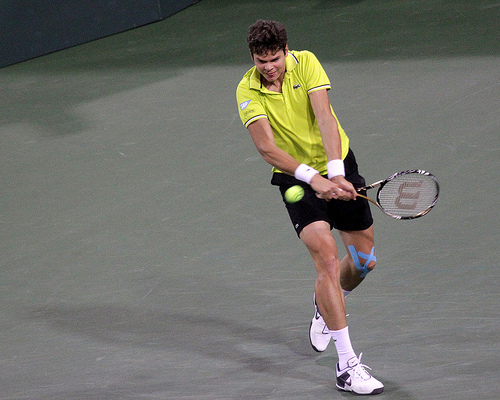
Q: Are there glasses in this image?
A: No, there are no glasses.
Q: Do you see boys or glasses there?
A: No, there are no glasses or boys.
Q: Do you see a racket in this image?
A: Yes, there is a racket.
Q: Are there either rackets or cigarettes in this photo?
A: Yes, there is a racket.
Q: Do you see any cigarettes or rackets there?
A: Yes, there is a racket.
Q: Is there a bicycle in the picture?
A: No, there are no bicycles.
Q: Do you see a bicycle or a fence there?
A: No, there are no bicycles or fences.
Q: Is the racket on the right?
A: Yes, the racket is on the right of the image.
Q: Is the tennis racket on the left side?
A: No, the tennis racket is on the right of the image.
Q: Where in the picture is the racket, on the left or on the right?
A: The racket is on the right of the image.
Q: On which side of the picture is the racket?
A: The racket is on the right of the image.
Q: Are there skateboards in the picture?
A: No, there are no skateboards.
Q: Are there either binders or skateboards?
A: No, there are no skateboards or binders.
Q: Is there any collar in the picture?
A: Yes, there is a collar.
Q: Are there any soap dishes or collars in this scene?
A: Yes, there is a collar.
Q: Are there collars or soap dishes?
A: Yes, there is a collar.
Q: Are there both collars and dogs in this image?
A: No, there is a collar but no dogs.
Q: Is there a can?
A: No, there are no cans.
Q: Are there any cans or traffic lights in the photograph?
A: No, there are no cans or traffic lights.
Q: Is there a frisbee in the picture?
A: No, there are no frisbees.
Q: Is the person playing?
A: Yes, the player is playing.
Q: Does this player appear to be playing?
A: Yes, the player is playing.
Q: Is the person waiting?
A: No, the player is playing.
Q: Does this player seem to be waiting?
A: No, the player is playing.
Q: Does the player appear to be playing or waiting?
A: The player is playing.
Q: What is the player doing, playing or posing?
A: The player is playing.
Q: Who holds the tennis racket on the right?
A: The player holds the racket.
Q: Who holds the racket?
A: The player holds the racket.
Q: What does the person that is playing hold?
A: The player holds the tennis racket.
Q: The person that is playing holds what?
A: The player holds the tennis racket.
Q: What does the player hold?
A: The player holds the tennis racket.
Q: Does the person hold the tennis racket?
A: Yes, the player holds the tennis racket.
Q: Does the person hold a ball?
A: No, the player holds the tennis racket.